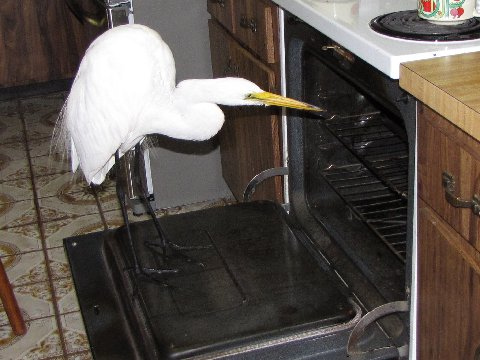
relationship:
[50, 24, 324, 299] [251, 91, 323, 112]
bird has beak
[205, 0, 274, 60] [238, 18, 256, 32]
drawer has handle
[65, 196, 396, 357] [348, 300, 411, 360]
oven door has hinge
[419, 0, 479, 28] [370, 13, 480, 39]
container on top of burner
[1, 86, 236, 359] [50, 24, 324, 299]
floor behind bird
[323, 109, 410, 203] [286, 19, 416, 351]
rack inside of oven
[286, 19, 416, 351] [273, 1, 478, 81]
oven has top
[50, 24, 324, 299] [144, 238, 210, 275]
bird has foot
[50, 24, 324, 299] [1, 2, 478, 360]
bird inside of house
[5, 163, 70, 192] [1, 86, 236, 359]
pattern on top of floor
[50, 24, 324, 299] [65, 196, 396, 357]
bird on top of oven door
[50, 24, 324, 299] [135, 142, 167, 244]
bird has leg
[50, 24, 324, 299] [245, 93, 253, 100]
bird has right eye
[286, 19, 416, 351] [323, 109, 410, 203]
oven has rack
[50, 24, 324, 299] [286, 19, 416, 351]
bird looking into oven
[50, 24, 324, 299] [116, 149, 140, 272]
bird has leg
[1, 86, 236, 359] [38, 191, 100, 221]
floor has tile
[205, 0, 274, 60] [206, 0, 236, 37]
drawer next to drawer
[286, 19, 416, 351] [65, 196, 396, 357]
oven has oven door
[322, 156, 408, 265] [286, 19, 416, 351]
rack inside of oven